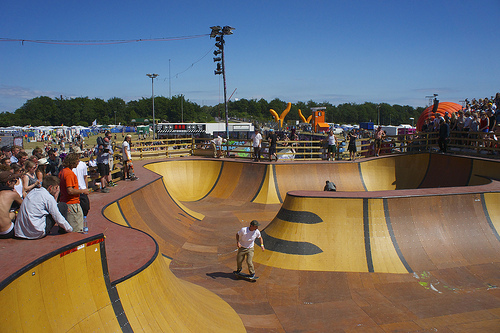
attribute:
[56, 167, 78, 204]
shirt — orange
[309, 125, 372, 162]
crowd — people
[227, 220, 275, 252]
shirt — white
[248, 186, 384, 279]
ramp — wood, painted, yellow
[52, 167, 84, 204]
shirt — orange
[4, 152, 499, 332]
ramp — wood, painted, yellow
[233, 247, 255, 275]
pants — long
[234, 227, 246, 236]
sleeve — short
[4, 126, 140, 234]
people — crowd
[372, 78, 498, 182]
crowd — people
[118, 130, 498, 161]
fence — wooden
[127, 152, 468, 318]
wood ramp — painted, yellow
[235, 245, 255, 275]
pants — khaki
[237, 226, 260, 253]
t shirt — white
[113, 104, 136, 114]
leaves — green